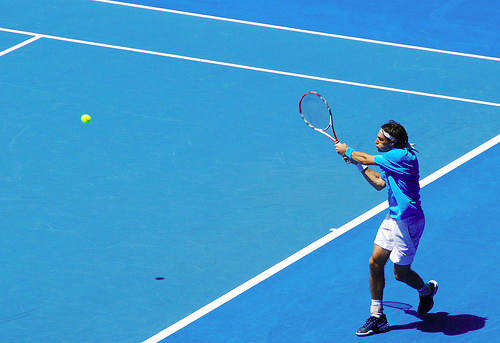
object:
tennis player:
[332, 119, 440, 338]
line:
[106, 1, 498, 61]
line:
[1, 25, 499, 109]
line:
[127, 127, 499, 341]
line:
[1, 32, 42, 71]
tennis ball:
[78, 111, 92, 127]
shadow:
[153, 274, 167, 284]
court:
[1, 0, 499, 343]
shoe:
[351, 311, 389, 338]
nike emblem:
[375, 317, 387, 329]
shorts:
[372, 209, 426, 267]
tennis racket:
[296, 88, 351, 164]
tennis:
[76, 82, 350, 167]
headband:
[377, 127, 401, 145]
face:
[374, 131, 385, 153]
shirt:
[374, 146, 424, 222]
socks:
[367, 297, 387, 318]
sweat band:
[342, 147, 356, 160]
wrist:
[343, 144, 354, 163]